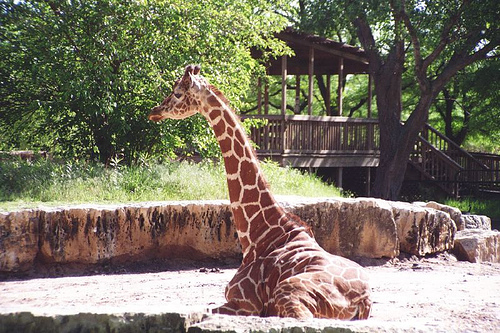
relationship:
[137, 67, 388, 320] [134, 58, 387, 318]
giraffe on ground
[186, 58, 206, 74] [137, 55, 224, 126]
horns on head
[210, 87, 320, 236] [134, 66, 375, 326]
mane on giraffe's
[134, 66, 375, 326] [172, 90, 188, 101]
giraffe's left eye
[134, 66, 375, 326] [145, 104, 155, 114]
giraffe's a nose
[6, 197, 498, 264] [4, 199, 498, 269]
stone long wall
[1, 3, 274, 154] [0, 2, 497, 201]
trees in background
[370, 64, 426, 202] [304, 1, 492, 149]
trunk of tree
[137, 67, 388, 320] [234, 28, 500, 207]
giraffe inside enclosure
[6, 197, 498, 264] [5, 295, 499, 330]
stone dirty embankment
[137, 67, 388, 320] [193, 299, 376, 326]
giraffe laying down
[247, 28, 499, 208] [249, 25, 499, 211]
brown wooden structure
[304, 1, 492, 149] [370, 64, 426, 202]
tree with trunk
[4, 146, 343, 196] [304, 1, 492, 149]
green bushy tree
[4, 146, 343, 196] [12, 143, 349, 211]
green overgrown grass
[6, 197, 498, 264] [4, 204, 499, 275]
stone large blocks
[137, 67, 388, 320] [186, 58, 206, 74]
giraffe brown horns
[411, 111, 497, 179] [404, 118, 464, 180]
stair with railings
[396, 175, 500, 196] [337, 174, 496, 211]
metal mesh fencing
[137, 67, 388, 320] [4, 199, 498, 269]
giraffe beside wall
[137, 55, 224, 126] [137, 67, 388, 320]
head of giraffe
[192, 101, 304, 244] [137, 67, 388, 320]
neck of giraffe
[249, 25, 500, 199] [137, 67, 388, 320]
structure next to giraffe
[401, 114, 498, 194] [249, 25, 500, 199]
stairs into structure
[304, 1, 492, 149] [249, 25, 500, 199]
tree beside structure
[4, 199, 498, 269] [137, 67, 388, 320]
wall near giraffe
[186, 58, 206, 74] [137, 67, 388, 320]
horns on giraffe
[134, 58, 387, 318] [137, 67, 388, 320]
ground on giraffe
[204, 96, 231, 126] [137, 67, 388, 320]
spots on giraffe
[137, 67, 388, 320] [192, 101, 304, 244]
giraffe has neck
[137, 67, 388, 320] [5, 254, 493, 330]
giraffe in dirt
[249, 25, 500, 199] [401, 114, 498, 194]
structure has stairs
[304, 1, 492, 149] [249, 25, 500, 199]
tree in front structure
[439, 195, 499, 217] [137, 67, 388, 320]
bush behind giraffe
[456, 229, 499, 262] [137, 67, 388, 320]
blocks behind giraffe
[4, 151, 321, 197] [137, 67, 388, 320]
hill behind giraffe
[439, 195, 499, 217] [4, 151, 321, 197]
bush on hill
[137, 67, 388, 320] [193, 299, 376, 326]
giraffe sitting down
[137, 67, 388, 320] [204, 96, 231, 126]
giraffe has spots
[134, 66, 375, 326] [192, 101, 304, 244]
giraffe's extended neck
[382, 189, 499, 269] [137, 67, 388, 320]
rocks behind giraffe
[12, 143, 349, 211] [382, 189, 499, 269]
grass behind rocks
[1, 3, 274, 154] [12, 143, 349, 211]
trees behind grass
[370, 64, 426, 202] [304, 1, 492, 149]
trunk on tree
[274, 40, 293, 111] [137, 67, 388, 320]
post behind giraffe